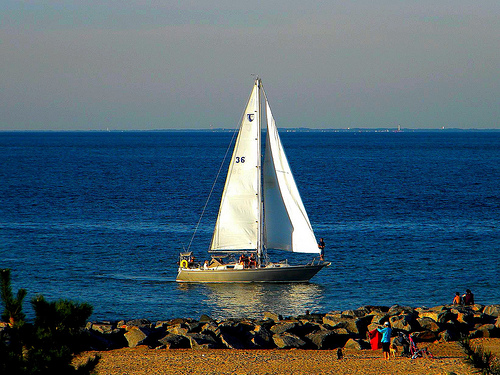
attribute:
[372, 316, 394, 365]
person — standing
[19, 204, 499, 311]
water — blue, calm, tranquil, serene, subdued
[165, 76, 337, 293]
boat — white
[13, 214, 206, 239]
reflection — white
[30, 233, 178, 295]
waves — small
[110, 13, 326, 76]
clouds — white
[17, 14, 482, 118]
sky — blue, clear, cloudless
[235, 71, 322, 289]
sailboat — white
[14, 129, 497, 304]
ocean — blue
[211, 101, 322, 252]
masts — white